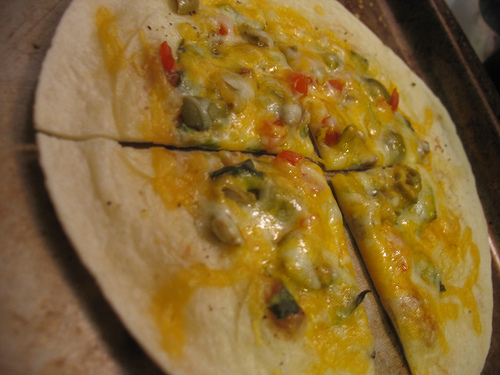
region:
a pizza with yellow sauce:
[3, 0, 496, 374]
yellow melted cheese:
[130, 8, 474, 363]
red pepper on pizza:
[148, 32, 186, 77]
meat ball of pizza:
[177, 88, 232, 139]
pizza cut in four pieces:
[27, 2, 499, 369]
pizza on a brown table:
[7, 8, 495, 373]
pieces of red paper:
[281, 56, 349, 154]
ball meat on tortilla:
[178, 60, 443, 332]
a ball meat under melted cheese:
[373, 124, 415, 169]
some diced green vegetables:
[316, 43, 369, 78]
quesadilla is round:
[32, 1, 495, 369]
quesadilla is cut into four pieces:
[32, 4, 494, 374]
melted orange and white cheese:
[150, 148, 377, 365]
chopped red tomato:
[157, 38, 177, 70]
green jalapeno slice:
[393, 164, 424, 203]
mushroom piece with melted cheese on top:
[177, 92, 222, 131]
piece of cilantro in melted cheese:
[209, 155, 264, 180]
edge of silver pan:
[425, 0, 498, 116]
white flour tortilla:
[37, 53, 173, 307]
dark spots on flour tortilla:
[145, 15, 174, 38]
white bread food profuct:
[33, 3, 498, 371]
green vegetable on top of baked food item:
[171, 93, 218, 134]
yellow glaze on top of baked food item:
[98, 3, 483, 368]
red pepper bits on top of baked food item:
[148, 35, 187, 76]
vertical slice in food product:
[246, 1, 435, 373]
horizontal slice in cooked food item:
[27, 111, 474, 198]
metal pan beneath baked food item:
[1, 1, 498, 370]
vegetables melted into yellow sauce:
[302, 63, 460, 305]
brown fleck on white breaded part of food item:
[93, 191, 127, 227]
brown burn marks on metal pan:
[11, 291, 75, 361]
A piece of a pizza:
[34, 143, 352, 373]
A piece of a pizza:
[341, 150, 493, 331]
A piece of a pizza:
[61, 2, 318, 153]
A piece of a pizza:
[271, 3, 478, 170]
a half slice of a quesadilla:
[31, 132, 379, 372]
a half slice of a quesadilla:
[331, 160, 491, 370]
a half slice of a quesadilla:
[255, 0, 465, 165]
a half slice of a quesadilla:
[30, 0, 315, 150]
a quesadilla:
[35, 0, 378, 372]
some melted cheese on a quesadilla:
[135, 1, 480, 356]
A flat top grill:
[0, 0, 495, 372]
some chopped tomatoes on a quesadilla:
[160, 40, 405, 325]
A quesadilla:
[259, 1, 491, 373]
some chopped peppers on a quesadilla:
[172, 0, 444, 325]